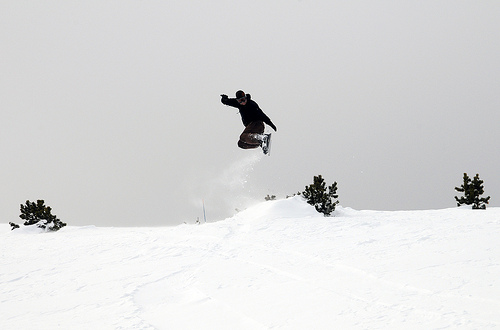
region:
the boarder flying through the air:
[214, 74, 286, 176]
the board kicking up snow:
[167, 151, 268, 215]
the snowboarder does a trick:
[210, 78, 282, 155]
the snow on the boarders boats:
[253, 131, 275, 156]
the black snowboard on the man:
[262, 132, 272, 157]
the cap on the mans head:
[235, 88, 248, 109]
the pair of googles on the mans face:
[236, 92, 246, 104]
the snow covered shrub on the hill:
[252, 167, 342, 225]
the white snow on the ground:
[96, 223, 496, 297]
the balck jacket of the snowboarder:
[216, 96, 278, 128]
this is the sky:
[102, 19, 161, 81]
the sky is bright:
[97, 165, 156, 201]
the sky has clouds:
[111, 158, 151, 193]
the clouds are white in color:
[98, 150, 169, 204]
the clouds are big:
[35, 128, 147, 195]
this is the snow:
[133, 253, 208, 272]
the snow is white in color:
[183, 255, 278, 315]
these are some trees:
[22, 173, 487, 228]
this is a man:
[216, 74, 278, 156]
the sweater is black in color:
[244, 110, 258, 122]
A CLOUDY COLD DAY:
[28, 15, 217, 193]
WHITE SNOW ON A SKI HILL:
[24, 202, 453, 324]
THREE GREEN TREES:
[1, 163, 496, 233]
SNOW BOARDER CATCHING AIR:
[197, 62, 321, 192]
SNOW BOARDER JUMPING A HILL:
[193, 67, 319, 177]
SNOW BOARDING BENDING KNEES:
[203, 49, 303, 179]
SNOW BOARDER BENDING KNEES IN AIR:
[204, 74, 316, 194]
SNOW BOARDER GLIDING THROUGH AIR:
[195, 69, 322, 196]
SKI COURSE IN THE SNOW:
[28, 215, 319, 323]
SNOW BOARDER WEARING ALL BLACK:
[196, 68, 304, 178]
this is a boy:
[214, 74, 272, 167]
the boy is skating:
[217, 85, 279, 162]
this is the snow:
[265, 225, 398, 310]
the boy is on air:
[211, 83, 288, 175]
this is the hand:
[217, 89, 239, 112]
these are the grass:
[303, 177, 338, 206]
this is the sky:
[53, 22, 184, 141]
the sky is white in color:
[26, 13, 181, 134]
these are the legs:
[237, 125, 272, 155]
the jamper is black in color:
[242, 101, 261, 121]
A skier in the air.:
[210, 74, 327, 197]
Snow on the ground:
[109, 228, 444, 316]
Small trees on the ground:
[11, 164, 498, 242]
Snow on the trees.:
[277, 168, 340, 223]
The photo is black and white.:
[56, 21, 470, 261]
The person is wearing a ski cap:
[233, 85, 249, 98]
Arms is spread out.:
[213, 87, 235, 109]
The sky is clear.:
[63, 30, 445, 183]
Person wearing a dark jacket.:
[223, 105, 279, 126]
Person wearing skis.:
[258, 130, 275, 160]